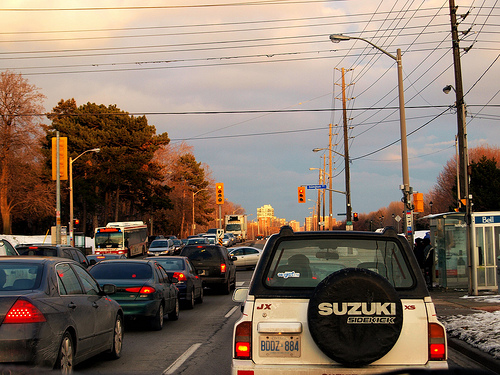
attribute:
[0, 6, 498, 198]
sky —  blue 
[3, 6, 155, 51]
clouds —  many,  white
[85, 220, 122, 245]
bus — large and white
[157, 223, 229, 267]
suv — black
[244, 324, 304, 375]
license — white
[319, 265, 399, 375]
tire — black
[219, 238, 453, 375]
truck — white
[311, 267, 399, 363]
tire — black, white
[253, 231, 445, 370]
truck — black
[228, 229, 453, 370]
truck — white, black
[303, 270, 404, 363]
tire — black